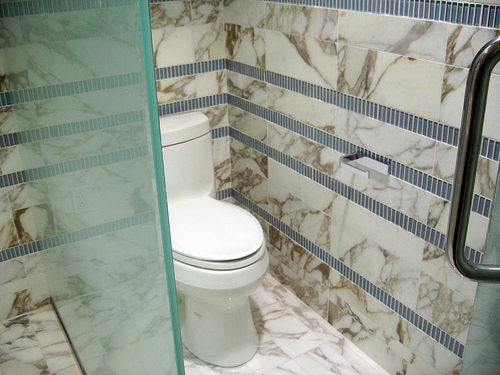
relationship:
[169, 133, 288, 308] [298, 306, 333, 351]
toilet on floor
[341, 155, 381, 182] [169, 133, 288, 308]
holder for toilet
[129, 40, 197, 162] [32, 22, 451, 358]
divider in bathroom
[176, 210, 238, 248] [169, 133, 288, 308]
lid on toilet